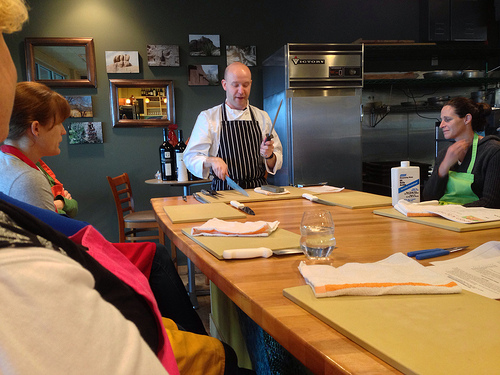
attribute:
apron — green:
[430, 127, 476, 216]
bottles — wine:
[145, 128, 199, 179]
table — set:
[126, 130, 473, 346]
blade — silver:
[247, 91, 309, 156]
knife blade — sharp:
[216, 170, 256, 205]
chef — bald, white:
[197, 54, 284, 139]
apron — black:
[207, 104, 273, 182]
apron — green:
[433, 141, 476, 207]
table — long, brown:
[152, 178, 496, 368]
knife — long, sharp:
[219, 171, 250, 201]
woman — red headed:
[1, 73, 75, 179]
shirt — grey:
[2, 150, 61, 221]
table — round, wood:
[133, 193, 289, 305]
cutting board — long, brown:
[193, 177, 319, 212]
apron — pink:
[62, 224, 178, 338]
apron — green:
[420, 136, 497, 223]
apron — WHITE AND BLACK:
[189, 57, 288, 195]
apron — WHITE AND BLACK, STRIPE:
[215, 109, 278, 188]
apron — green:
[445, 139, 489, 214]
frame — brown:
[81, 33, 119, 110]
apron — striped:
[200, 109, 266, 174]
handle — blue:
[403, 232, 447, 278]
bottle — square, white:
[385, 145, 434, 230]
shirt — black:
[430, 140, 494, 180]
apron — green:
[434, 155, 481, 204]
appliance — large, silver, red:
[282, 45, 353, 165]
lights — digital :
[313, 51, 392, 95]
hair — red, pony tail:
[18, 75, 39, 129]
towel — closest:
[307, 259, 384, 290]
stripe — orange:
[318, 273, 446, 293]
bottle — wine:
[142, 115, 202, 200]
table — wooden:
[249, 273, 277, 299]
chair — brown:
[100, 167, 142, 237]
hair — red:
[21, 91, 58, 128]